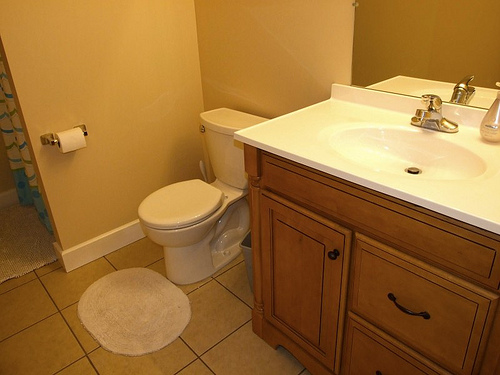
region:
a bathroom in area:
[5, 0, 494, 364]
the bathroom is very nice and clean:
[6, 0, 496, 366]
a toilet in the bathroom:
[130, 99, 260, 279]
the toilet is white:
[133, 109, 265, 285]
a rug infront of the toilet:
[66, 266, 199, 356]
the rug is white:
[78, 268, 193, 368]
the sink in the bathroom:
[216, 85, 498, 223]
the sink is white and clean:
[231, 78, 498, 225]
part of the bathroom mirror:
[354, 3, 498, 122]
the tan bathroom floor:
[6, 226, 330, 371]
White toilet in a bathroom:
[126, 103, 282, 288]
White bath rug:
[78, 263, 192, 358]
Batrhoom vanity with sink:
[233, 74, 496, 355]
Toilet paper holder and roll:
[38, 123, 94, 153]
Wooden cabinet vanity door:
[248, 182, 345, 372]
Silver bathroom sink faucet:
[406, 89, 460, 135]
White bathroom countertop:
[228, 78, 497, 236]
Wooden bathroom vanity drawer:
[351, 233, 489, 373]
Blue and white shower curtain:
[0, 45, 58, 240]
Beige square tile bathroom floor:
[3, 215, 292, 371]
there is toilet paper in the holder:
[40, 116, 95, 164]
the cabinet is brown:
[266, 201, 351, 343]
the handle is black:
[387, 295, 429, 322]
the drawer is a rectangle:
[348, 241, 487, 369]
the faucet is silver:
[409, 90, 443, 134]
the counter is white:
[274, 108, 335, 144]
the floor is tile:
[198, 298, 253, 353]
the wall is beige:
[105, 85, 162, 170]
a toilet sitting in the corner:
[134, 101, 265, 289]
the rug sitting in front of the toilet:
[76, 268, 193, 361]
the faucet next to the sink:
[411, 95, 458, 135]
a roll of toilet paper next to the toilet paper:
[55, 129, 87, 152]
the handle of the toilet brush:
[194, 157, 209, 183]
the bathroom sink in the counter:
[343, 128, 483, 194]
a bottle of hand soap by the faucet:
[473, 78, 498, 143]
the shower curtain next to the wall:
[3, 71, 48, 221]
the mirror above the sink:
[350, 3, 496, 108]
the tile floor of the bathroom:
[6, 250, 302, 372]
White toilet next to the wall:
[134, 103, 283, 285]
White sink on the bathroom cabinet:
[232, 62, 498, 236]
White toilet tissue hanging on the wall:
[36, 120, 94, 155]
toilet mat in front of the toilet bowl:
[75, 262, 195, 355]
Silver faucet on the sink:
[407, 84, 457, 136]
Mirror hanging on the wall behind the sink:
[350, 1, 499, 110]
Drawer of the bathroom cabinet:
[350, 237, 489, 368]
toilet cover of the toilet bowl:
[132, 176, 224, 236]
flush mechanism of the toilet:
[197, 123, 210, 134]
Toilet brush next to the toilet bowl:
[195, 156, 212, 185]